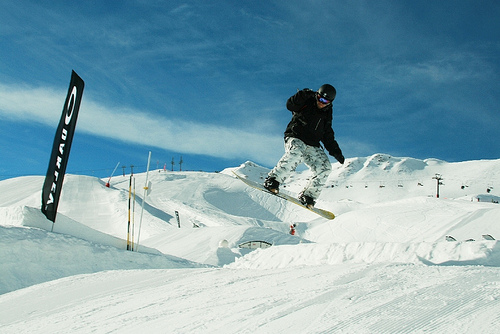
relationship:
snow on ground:
[115, 248, 397, 301] [40, 195, 484, 330]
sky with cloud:
[3, 2, 498, 154] [7, 74, 272, 164]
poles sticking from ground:
[118, 157, 153, 257] [0, 223, 483, 331]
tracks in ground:
[90, 266, 491, 332] [2, 152, 498, 331]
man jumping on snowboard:
[271, 87, 347, 205] [238, 175, 335, 219]